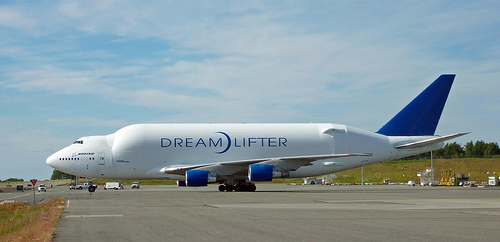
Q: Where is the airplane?
A: Parked at the airport.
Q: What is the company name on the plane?
A: Dream Lifter.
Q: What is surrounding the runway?
A: Grass.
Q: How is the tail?
A: Tall and blue.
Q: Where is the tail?
A: At the back of plane.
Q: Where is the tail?
A: Near the back wings.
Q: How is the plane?
A: White.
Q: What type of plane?
A: White plane.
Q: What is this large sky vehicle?
A: Airplane.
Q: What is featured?
A: A Dream Lifter.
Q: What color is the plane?
A: White.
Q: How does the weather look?
A: Cloudy.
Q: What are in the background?
A: Trees.